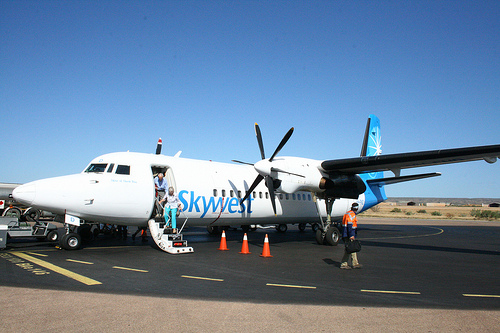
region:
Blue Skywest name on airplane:
[158, 189, 267, 217]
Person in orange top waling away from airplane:
[337, 200, 367, 277]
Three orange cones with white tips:
[212, 229, 282, 264]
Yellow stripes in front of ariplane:
[24, 254, 499, 301]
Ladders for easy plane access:
[142, 165, 200, 256]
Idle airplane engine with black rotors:
[224, 121, 307, 221]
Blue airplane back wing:
[349, 110, 404, 212]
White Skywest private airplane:
[22, 116, 497, 239]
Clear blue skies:
[0, 0, 493, 199]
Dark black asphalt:
[0, 227, 497, 289]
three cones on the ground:
[220, 229, 280, 260]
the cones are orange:
[206, 227, 298, 263]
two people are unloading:
[136, 156, 192, 250]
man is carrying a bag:
[320, 194, 374, 276]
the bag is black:
[338, 234, 374, 249]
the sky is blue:
[30, 21, 206, 123]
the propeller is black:
[241, 122, 299, 227]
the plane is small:
[34, 119, 498, 319]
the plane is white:
[33, 120, 424, 297]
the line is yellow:
[16, 254, 107, 306]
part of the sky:
[330, 33, 391, 94]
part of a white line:
[259, 272, 313, 303]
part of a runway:
[290, 317, 318, 329]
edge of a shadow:
[301, 302, 333, 312]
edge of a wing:
[406, 141, 463, 155]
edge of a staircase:
[117, 214, 176, 260]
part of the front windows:
[78, 157, 131, 183]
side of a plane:
[166, 148, 256, 208]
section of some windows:
[206, 184, 274, 209]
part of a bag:
[341, 245, 371, 269]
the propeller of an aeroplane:
[222, 107, 311, 222]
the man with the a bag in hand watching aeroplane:
[332, 196, 367, 273]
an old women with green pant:
[157, 182, 186, 234]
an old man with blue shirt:
[152, 168, 167, 209]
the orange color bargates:
[215, 226, 277, 260]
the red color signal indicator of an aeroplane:
[147, 134, 174, 160]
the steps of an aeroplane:
[145, 206, 197, 259]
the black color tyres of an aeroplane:
[56, 225, 80, 256]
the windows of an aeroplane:
[205, 185, 243, 201]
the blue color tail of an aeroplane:
[346, 103, 398, 213]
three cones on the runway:
[210, 223, 281, 263]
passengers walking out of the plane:
[151, 168, 186, 237]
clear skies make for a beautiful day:
[0, 0, 495, 120]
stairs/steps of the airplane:
[147, 215, 196, 257]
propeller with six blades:
[222, 118, 304, 215]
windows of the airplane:
[209, 185, 319, 204]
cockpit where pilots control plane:
[79, 159, 139, 179]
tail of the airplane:
[354, 110, 391, 211]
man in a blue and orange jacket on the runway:
[336, 200, 370, 275]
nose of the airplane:
[8, 170, 121, 219]